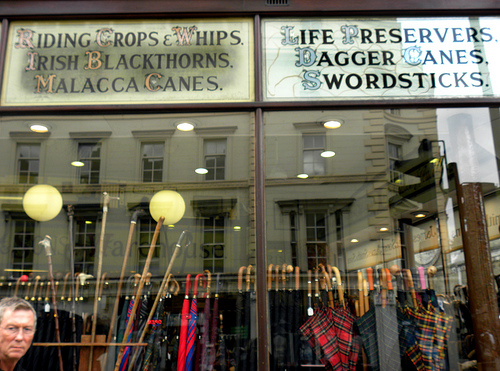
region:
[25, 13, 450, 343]
this is a storefront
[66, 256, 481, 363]
these are a row of umbrellas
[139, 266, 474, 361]
the umbrellas are multicolored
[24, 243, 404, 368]
this is an umbrella store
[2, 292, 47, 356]
this is a man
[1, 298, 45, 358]
the man looks very serious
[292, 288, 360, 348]
this umbrella is plaid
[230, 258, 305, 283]
the handles are brown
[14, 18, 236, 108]
the letters are black and gold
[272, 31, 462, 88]
the letters are silver and black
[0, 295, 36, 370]
the head of a man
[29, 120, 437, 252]
the recessed lighting in the store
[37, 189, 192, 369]
the wooden canes in the window display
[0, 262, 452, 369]
the row of umbrellas hanging by their handles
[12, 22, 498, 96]
the words above the window display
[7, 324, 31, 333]
the man's eyes on his face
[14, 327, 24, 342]
the nose on the man's face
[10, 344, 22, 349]
the mouth on the man's face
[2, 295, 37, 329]
the hair on the man's head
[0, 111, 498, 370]
the reflection in the window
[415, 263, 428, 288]
A pink umbrella handle.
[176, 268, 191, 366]
A red umbrella with red handle.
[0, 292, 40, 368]
A man looking ahead.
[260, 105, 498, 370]
One side of a store window.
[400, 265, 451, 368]
A orange and yellow plaid umbrella.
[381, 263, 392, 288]
A orange handle of a umbrella.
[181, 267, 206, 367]
A red and blue umbrella.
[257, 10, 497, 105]
A sign on a building.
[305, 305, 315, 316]
A white tag on a umbrella.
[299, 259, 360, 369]
A red and black plaid umbrella.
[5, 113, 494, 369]
A reflection in the building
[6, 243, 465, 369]
Umbrella in the store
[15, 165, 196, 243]
Yellow lights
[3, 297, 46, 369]
A person looking in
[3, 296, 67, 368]
Person is white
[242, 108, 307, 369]
A brown pole here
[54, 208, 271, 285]
Words on a sign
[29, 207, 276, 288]
The sign is yellow and black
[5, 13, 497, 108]
Sign on top of window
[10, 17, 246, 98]
Font is brown and black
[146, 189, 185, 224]
Globe light illuminating yellow.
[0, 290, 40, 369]
Man's face near store window.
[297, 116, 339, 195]
Recessed lighting inside of store.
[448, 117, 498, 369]
Brown pole support for building.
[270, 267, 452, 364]
Various colored umbrellas inside store.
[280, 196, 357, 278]
Second story building window.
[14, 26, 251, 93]
Old fashioned window advertisement.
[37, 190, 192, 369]
Various sizes of men's walking sticks.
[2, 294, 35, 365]
Man facing camera in photo.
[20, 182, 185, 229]
Two globe light fixtures illuminating in store.